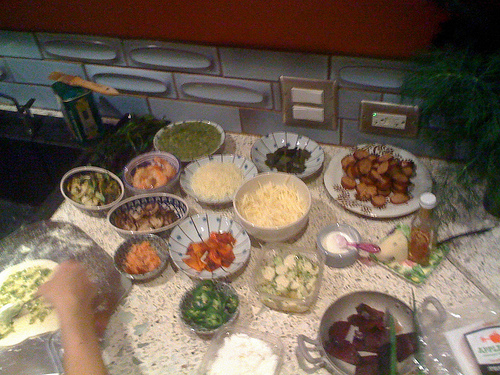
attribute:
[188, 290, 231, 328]
slices — jalapeno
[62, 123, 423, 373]
food — assorted